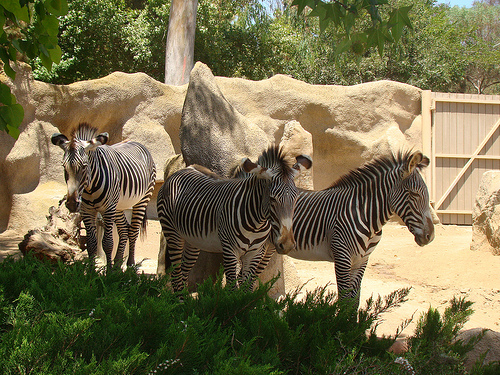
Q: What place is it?
A: It is a pen.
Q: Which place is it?
A: It is a pen.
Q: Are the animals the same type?
A: Yes, all the animals are zebras.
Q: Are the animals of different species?
A: No, all the animals are zebras.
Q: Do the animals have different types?
A: No, all the animals are zebras.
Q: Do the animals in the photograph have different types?
A: No, all the animals are zebras.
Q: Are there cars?
A: No, there are no cars.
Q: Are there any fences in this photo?
A: Yes, there is a fence.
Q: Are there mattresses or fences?
A: Yes, there is a fence.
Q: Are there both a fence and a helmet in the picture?
A: No, there is a fence but no helmets.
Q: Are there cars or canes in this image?
A: No, there are no cars or canes.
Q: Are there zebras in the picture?
A: Yes, there is a zebra.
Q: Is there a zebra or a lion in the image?
A: Yes, there is a zebra.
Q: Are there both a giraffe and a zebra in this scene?
A: No, there is a zebra but no giraffes.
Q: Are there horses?
A: No, there are no horses.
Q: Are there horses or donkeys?
A: No, there are no horses or donkeys.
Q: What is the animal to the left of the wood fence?
A: The animal is a zebra.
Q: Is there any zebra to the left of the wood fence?
A: Yes, there is a zebra to the left of the fence.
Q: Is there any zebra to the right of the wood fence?
A: No, the zebra is to the left of the fence.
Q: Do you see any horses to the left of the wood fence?
A: No, there is a zebra to the left of the fence.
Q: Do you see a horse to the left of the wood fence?
A: No, there is a zebra to the left of the fence.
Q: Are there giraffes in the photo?
A: No, there are no giraffes.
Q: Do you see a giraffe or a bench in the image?
A: No, there are no giraffes or benches.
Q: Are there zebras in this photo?
A: Yes, there is a zebra.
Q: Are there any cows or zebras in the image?
A: Yes, there is a zebra.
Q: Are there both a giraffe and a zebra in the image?
A: No, there is a zebra but no giraffes.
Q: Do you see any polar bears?
A: No, there are no polar bears.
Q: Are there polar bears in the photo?
A: No, there are no polar bears.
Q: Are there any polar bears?
A: No, there are no polar bears.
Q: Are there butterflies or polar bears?
A: No, there are no polar bears or butterflies.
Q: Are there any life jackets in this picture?
A: No, there are no life jackets.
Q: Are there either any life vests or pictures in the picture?
A: No, there are no life vests or pictures.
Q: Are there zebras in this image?
A: Yes, there are zebras.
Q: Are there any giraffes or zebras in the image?
A: Yes, there are zebras.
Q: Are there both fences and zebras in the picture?
A: Yes, there are both zebras and a fence.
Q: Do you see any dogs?
A: No, there are no dogs.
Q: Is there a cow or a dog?
A: No, there are no dogs or cows.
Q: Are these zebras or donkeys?
A: These are zebras.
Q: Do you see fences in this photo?
A: Yes, there is a fence.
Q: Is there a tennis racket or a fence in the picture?
A: Yes, there is a fence.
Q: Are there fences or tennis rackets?
A: Yes, there is a fence.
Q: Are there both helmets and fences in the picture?
A: No, there is a fence but no helmets.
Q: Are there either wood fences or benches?
A: Yes, there is a wood fence.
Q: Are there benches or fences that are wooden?
A: Yes, the fence is wooden.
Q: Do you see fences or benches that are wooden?
A: Yes, the fence is wooden.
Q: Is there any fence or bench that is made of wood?
A: Yes, the fence is made of wood.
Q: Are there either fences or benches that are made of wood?
A: Yes, the fence is made of wood.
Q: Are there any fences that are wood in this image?
A: Yes, there is a wood fence.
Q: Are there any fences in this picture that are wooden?
A: Yes, there is a fence that is wooden.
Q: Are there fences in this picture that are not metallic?
A: Yes, there is a wooden fence.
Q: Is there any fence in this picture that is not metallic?
A: Yes, there is a wooden fence.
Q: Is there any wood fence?
A: Yes, there is a fence that is made of wood.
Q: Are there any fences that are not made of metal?
A: Yes, there is a fence that is made of wood.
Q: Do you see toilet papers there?
A: No, there are no toilet papers.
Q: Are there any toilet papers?
A: No, there are no toilet papers.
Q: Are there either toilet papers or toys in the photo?
A: No, there are no toilet papers or toys.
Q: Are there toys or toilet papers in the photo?
A: No, there are no toilet papers or toys.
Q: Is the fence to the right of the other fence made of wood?
A: Yes, the fence is made of wood.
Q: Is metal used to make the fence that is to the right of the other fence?
A: No, the fence is made of wood.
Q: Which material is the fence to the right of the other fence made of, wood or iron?
A: The fence is made of wood.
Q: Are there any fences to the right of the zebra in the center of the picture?
A: Yes, there is a fence to the right of the zebra.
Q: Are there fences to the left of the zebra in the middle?
A: No, the fence is to the right of the zebra.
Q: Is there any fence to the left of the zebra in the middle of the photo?
A: No, the fence is to the right of the zebra.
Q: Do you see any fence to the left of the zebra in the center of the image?
A: No, the fence is to the right of the zebra.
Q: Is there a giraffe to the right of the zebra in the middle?
A: No, there is a fence to the right of the zebra.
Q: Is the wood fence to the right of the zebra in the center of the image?
A: Yes, the fence is to the right of the zebra.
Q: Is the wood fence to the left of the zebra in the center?
A: No, the fence is to the right of the zebra.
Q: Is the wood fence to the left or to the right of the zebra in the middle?
A: The fence is to the right of the zebra.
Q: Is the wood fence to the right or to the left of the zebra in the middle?
A: The fence is to the right of the zebra.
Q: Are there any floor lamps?
A: No, there are no floor lamps.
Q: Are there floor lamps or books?
A: No, there are no floor lamps or books.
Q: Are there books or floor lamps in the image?
A: No, there are no floor lamps or books.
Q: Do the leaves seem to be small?
A: Yes, the leaves are small.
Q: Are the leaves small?
A: Yes, the leaves are small.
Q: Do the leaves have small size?
A: Yes, the leaves are small.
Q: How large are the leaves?
A: The leaves are small.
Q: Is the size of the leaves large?
A: No, the leaves are small.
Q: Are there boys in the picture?
A: No, there are no boys.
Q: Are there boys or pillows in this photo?
A: No, there are no boys or pillows.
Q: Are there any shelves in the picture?
A: No, there are no shelves.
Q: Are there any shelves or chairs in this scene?
A: No, there are no shelves or chairs.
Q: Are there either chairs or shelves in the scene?
A: No, there are no shelves or chairs.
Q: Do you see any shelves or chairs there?
A: No, there are no shelves or chairs.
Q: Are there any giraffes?
A: No, there are no giraffes.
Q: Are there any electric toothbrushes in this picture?
A: No, there are no electric toothbrushes.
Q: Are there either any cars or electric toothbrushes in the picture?
A: No, there are no electric toothbrushes or cars.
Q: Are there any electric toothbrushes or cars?
A: No, there are no electric toothbrushes or cars.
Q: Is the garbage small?
A: Yes, the garbage is small.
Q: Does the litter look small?
A: Yes, the litter is small.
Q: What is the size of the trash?
A: The trash is small.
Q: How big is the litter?
A: The litter is small.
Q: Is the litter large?
A: No, the litter is small.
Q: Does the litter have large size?
A: No, the litter is small.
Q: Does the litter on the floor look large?
A: No, the litter is small.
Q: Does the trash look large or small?
A: The trash is small.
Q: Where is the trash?
A: The trash is on the floor.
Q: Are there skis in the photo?
A: No, there are no skis.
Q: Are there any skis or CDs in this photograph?
A: No, there are no skis or cds.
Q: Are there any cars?
A: No, there are no cars.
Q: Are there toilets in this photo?
A: No, there are no toilets.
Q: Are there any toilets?
A: No, there are no toilets.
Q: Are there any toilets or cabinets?
A: No, there are no toilets or cabinets.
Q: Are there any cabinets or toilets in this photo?
A: No, there are no toilets or cabinets.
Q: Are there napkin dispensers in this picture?
A: No, there are no napkin dispensers.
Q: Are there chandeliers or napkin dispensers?
A: No, there are no napkin dispensers or chandeliers.